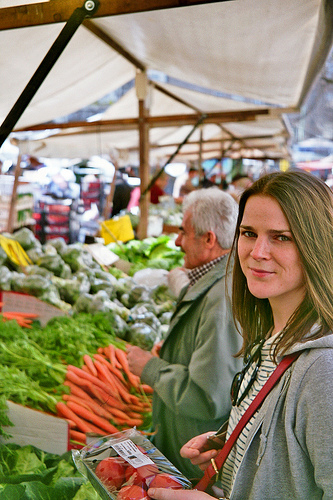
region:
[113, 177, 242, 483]
middle aged man laughing at salad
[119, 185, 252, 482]
middle aged man laughing at vegetables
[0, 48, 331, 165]
tent/umbrella-style roof @ large farmers market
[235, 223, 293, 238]
youngish woman with very straight but strange eyebrows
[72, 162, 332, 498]
youngish woman kind of smirking w/ a pack of tomatoes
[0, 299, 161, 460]
a whole mess of carrots w/ tops attached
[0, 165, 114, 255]
boxed+packaged vegetables in the blurry distance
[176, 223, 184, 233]
one brushy black brow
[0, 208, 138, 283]
signs on yellow paper taped to sticks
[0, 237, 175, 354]
broccoli in cellophane, lots of it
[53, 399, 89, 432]
an orange carrot root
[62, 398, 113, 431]
an orange carrot root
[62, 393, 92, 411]
an orange carrot root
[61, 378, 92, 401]
an orange carrot root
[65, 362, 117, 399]
an orange carrot root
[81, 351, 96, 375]
an orange carrot root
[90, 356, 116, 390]
an orange carrot root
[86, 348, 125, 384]
an orange carrot root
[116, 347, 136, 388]
an orange carrot root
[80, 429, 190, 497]
a package of tomatoes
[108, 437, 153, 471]
White label on package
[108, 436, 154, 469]
White label with black print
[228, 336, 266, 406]
Black sunglasses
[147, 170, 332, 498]
Woman wearing a stripped shirt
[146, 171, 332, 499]
Woman wearing a grey jacket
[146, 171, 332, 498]
Woman has brown hair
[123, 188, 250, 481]
Man wearing a grey jacket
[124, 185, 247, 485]
Man wearing a plaid shirt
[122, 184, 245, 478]
Man has black eyebrows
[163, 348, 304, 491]
Red strap with gold buckle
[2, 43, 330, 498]
people at an outdoor farmers market-type event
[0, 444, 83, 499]
green vegetable leaves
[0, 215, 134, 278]
yellow signs among produce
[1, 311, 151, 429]
large carrots piled on top of each other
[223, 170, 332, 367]
a woman with shoulder length brown hair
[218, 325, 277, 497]
woman wearing a shirt that is striped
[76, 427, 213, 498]
woman holding a package of tomatoes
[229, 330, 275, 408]
sunglasses hung from woman's collar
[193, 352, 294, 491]
red strap across woman's upper body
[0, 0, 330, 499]
produce shaded by large umbrellas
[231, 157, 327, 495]
This is a person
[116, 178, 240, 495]
This is a person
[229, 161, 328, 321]
Head of a person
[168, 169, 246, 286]
Head of a person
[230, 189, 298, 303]
Face of a person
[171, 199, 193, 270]
Face of a person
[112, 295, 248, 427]
Hand of a person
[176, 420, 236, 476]
Hand of a person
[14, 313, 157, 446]
These are yellow carrots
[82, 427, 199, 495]
These are red berries